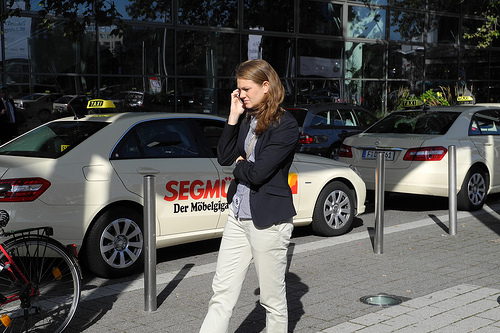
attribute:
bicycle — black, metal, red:
[0, 206, 84, 331]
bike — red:
[2, 222, 96, 332]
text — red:
[160, 176, 235, 203]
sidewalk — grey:
[37, 195, 498, 330]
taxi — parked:
[9, 82, 430, 268]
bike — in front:
[2, 225, 84, 331]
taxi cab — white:
[351, 89, 499, 199]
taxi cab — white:
[4, 96, 366, 259]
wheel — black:
[5, 226, 92, 331]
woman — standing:
[194, 44, 309, 331]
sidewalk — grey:
[406, 276, 489, 328]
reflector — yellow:
[50, 267, 60, 279]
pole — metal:
[143, 172, 158, 310]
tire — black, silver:
[0, 232, 86, 328]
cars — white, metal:
[15, 100, 492, 235]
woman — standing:
[224, 54, 299, 327]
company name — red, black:
[163, 173, 235, 214]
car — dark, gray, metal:
[279, 89, 386, 165]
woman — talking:
[195, 53, 298, 332]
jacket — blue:
[221, 107, 306, 227]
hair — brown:
[235, 55, 287, 136]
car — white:
[2, 111, 367, 278]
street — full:
[0, 114, 484, 307]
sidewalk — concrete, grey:
[3, 200, 484, 330]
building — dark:
[0, 1, 483, 116]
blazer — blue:
[220, 101, 305, 226]